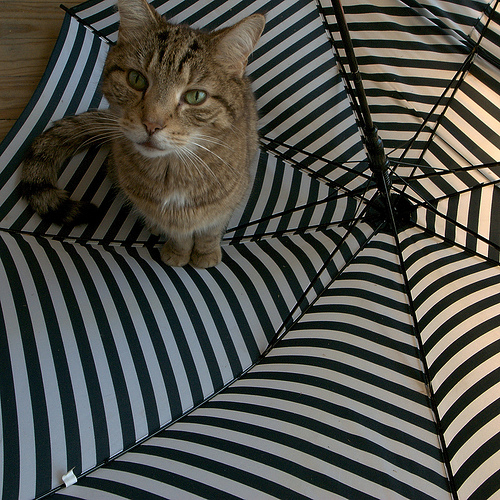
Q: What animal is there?
A: Cat.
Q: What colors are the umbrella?
A: Black and white.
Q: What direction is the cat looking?
A: Up.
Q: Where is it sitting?
A: In the umbrella.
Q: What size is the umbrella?
A: Large.